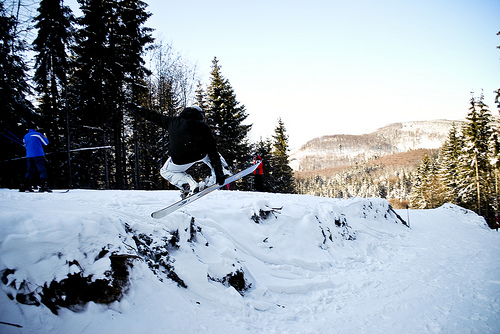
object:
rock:
[10, 212, 232, 324]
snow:
[110, 209, 191, 244]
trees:
[468, 94, 498, 216]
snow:
[454, 141, 481, 202]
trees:
[35, 0, 140, 135]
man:
[123, 96, 234, 197]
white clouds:
[366, 30, 429, 60]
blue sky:
[2, 0, 498, 147]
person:
[10, 117, 59, 192]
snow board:
[151, 157, 261, 217]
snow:
[200, 254, 260, 301]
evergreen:
[267, 117, 297, 192]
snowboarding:
[150, 175, 254, 217]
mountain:
[298, 118, 498, 193]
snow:
[396, 117, 454, 147]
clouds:
[184, 7, 209, 36]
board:
[147, 176, 239, 218]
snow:
[398, 207, 467, 256]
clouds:
[248, 25, 363, 100]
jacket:
[22, 127, 48, 161]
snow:
[385, 243, 483, 323]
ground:
[3, 178, 483, 318]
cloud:
[183, 8, 473, 146]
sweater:
[135, 101, 230, 180]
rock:
[340, 196, 408, 231]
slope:
[3, 175, 484, 322]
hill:
[246, 185, 342, 223]